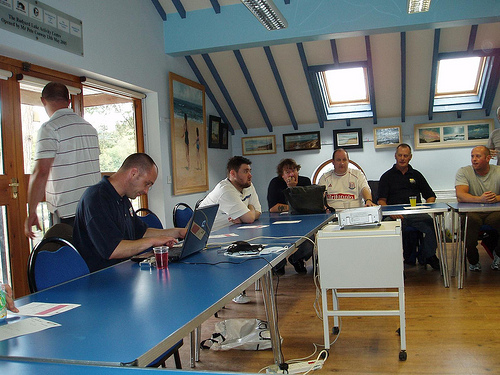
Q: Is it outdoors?
A: Yes, it is outdoors.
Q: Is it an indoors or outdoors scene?
A: It is outdoors.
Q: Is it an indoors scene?
A: No, it is outdoors.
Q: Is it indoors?
A: No, it is outdoors.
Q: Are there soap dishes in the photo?
A: No, there are no soap dishes.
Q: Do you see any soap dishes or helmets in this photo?
A: No, there are no soap dishes or helmets.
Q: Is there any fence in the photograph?
A: No, there are no fences.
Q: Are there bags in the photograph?
A: Yes, there is a bag.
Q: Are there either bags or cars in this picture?
A: Yes, there is a bag.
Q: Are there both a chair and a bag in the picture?
A: Yes, there are both a bag and a chair.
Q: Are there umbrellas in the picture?
A: No, there are no umbrellas.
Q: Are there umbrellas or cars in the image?
A: No, there are no umbrellas or cars.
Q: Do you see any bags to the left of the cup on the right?
A: Yes, there is a bag to the left of the cup.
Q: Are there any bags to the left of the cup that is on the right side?
A: Yes, there is a bag to the left of the cup.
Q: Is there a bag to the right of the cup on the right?
A: No, the bag is to the left of the cup.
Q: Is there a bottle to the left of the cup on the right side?
A: No, there is a bag to the left of the cup.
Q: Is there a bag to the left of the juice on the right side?
A: Yes, there is a bag to the left of the juice.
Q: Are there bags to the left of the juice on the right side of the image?
A: Yes, there is a bag to the left of the juice.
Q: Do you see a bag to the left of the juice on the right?
A: Yes, there is a bag to the left of the juice.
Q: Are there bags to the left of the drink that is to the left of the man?
A: Yes, there is a bag to the left of the juice.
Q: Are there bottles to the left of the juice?
A: No, there is a bag to the left of the juice.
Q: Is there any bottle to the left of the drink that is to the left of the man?
A: No, there is a bag to the left of the juice.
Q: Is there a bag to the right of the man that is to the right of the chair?
A: Yes, there is a bag to the right of the man.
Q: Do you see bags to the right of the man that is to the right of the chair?
A: Yes, there is a bag to the right of the man.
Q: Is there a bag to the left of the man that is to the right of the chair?
A: No, the bag is to the right of the man.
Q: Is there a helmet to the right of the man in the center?
A: No, there is a bag to the right of the man.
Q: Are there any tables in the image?
A: Yes, there is a table.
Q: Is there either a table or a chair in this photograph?
A: Yes, there is a table.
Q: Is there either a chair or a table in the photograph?
A: Yes, there is a table.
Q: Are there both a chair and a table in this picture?
A: Yes, there are both a table and a chair.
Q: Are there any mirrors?
A: No, there are no mirrors.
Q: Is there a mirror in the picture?
A: No, there are no mirrors.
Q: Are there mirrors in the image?
A: No, there are no mirrors.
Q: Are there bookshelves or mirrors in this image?
A: No, there are no mirrors or bookshelves.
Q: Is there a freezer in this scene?
A: No, there are no refrigerators.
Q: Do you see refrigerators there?
A: No, there are no refrigerators.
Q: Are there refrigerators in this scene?
A: No, there are no refrigerators.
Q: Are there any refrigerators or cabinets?
A: No, there are no refrigerators or cabinets.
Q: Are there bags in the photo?
A: Yes, there is a bag.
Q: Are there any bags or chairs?
A: Yes, there is a bag.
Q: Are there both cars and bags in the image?
A: No, there is a bag but no cars.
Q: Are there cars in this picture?
A: No, there are no cars.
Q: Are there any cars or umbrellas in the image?
A: No, there are no cars or umbrellas.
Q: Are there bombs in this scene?
A: No, there are no bombs.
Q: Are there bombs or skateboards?
A: No, there are no bombs or skateboards.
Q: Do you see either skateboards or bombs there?
A: No, there are no bombs or skateboards.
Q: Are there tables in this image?
A: Yes, there is a table.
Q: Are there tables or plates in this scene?
A: Yes, there is a table.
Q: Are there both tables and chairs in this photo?
A: Yes, there are both a table and chairs.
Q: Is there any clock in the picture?
A: No, there are no clocks.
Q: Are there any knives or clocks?
A: No, there are no clocks or knives.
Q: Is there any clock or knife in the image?
A: No, there are no clocks or knives.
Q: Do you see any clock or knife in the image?
A: No, there are no clocks or knives.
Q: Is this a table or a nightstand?
A: This is a table.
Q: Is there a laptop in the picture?
A: Yes, there is a laptop.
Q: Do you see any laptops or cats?
A: Yes, there is a laptop.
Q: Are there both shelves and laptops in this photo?
A: No, there is a laptop but no shelves.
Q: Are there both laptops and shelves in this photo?
A: No, there is a laptop but no shelves.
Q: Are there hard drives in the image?
A: No, there are no hard drives.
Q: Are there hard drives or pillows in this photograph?
A: No, there are no hard drives or pillows.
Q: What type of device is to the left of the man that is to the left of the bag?
A: The device is a laptop.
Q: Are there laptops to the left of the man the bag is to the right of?
A: Yes, there is a laptop to the left of the man.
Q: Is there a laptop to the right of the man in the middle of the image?
A: No, the laptop is to the left of the man.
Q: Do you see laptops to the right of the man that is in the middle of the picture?
A: No, the laptop is to the left of the man.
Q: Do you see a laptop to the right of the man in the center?
A: No, the laptop is to the left of the man.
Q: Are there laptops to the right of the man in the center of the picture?
A: No, the laptop is to the left of the man.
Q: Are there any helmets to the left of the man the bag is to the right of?
A: No, there is a laptop to the left of the man.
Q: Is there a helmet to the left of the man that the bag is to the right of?
A: No, there is a laptop to the left of the man.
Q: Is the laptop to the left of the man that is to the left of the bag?
A: Yes, the laptop is to the left of the man.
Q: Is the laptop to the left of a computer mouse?
A: No, the laptop is to the left of the man.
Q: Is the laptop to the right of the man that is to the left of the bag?
A: No, the laptop is to the left of the man.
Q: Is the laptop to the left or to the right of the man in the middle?
A: The laptop is to the left of the man.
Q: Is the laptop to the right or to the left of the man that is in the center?
A: The laptop is to the left of the man.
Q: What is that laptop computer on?
A: The laptop computer is on the table.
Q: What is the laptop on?
A: The laptop computer is on the table.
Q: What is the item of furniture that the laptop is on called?
A: The piece of furniture is a table.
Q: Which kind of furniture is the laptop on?
A: The laptop is on the table.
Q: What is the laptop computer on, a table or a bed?
A: The laptop computer is on a table.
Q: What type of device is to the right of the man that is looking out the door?
A: The device is a laptop.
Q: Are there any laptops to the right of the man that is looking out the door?
A: Yes, there is a laptop to the right of the man.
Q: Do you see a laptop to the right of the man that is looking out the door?
A: Yes, there is a laptop to the right of the man.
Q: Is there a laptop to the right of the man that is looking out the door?
A: Yes, there is a laptop to the right of the man.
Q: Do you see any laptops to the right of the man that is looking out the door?
A: Yes, there is a laptop to the right of the man.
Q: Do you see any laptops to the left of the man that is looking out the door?
A: No, the laptop is to the right of the man.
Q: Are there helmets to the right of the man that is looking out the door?
A: No, there is a laptop to the right of the man.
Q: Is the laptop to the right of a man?
A: Yes, the laptop is to the right of a man.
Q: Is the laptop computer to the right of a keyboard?
A: No, the laptop computer is to the right of a man.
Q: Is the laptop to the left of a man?
A: No, the laptop is to the right of a man.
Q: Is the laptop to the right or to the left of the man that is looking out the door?
A: The laptop is to the right of the man.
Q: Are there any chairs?
A: Yes, there is a chair.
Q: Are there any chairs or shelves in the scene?
A: Yes, there is a chair.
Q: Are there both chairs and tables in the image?
A: Yes, there are both a chair and a table.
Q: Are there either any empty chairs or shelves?
A: Yes, there is an empty chair.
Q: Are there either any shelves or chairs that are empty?
A: Yes, the chair is empty.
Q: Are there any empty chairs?
A: Yes, there is an empty chair.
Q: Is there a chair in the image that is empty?
A: Yes, there is a chair that is empty.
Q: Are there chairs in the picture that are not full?
A: Yes, there is a empty chair.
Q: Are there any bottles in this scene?
A: No, there are no bottles.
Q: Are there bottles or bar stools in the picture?
A: No, there are no bottles or bar stools.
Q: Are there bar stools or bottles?
A: No, there are no bottles or bar stools.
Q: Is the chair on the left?
A: Yes, the chair is on the left of the image.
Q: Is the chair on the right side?
A: No, the chair is on the left of the image.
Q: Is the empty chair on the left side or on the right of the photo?
A: The chair is on the left of the image.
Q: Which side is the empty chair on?
A: The chair is on the left of the image.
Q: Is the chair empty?
A: Yes, the chair is empty.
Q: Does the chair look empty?
A: Yes, the chair is empty.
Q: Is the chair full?
A: No, the chair is empty.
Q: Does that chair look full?
A: No, the chair is empty.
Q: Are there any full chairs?
A: No, there is a chair but it is empty.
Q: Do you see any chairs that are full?
A: No, there is a chair but it is empty.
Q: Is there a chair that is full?
A: No, there is a chair but it is empty.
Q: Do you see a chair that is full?
A: No, there is a chair but it is empty.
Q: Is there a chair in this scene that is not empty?
A: No, there is a chair but it is empty.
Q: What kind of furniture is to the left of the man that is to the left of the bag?
A: The piece of furniture is a chair.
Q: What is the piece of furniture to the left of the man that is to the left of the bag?
A: The piece of furniture is a chair.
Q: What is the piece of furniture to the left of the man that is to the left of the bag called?
A: The piece of furniture is a chair.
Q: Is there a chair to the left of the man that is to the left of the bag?
A: Yes, there is a chair to the left of the man.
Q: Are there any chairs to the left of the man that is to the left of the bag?
A: Yes, there is a chair to the left of the man.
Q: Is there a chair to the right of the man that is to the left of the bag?
A: No, the chair is to the left of the man.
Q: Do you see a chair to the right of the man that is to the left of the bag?
A: No, the chair is to the left of the man.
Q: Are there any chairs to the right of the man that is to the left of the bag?
A: No, the chair is to the left of the man.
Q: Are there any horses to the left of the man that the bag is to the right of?
A: No, there is a chair to the left of the man.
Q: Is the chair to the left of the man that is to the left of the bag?
A: Yes, the chair is to the left of the man.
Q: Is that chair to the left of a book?
A: No, the chair is to the left of the man.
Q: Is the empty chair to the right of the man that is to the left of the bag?
A: No, the chair is to the left of the man.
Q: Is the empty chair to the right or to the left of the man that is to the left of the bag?
A: The chair is to the left of the man.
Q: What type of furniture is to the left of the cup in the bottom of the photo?
A: The piece of furniture is a chair.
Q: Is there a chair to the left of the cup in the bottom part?
A: Yes, there is a chair to the left of the cup.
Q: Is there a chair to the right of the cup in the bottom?
A: No, the chair is to the left of the cup.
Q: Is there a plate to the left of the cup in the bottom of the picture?
A: No, there is a chair to the left of the cup.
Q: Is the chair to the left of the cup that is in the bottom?
A: Yes, the chair is to the left of the cup.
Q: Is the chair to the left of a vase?
A: No, the chair is to the left of the cup.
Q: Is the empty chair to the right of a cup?
A: No, the chair is to the left of a cup.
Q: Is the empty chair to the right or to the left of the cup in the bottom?
A: The chair is to the left of the cup.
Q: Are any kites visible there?
A: No, there are no kites.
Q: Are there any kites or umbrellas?
A: No, there are no kites or umbrellas.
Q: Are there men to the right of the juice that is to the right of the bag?
A: Yes, there is a man to the right of the juice.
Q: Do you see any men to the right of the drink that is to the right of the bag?
A: Yes, there is a man to the right of the juice.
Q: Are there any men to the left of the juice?
A: No, the man is to the right of the juice.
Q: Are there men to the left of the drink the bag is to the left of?
A: No, the man is to the right of the juice.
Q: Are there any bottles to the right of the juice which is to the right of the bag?
A: No, there is a man to the right of the juice.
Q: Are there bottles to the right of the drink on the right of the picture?
A: No, there is a man to the right of the juice.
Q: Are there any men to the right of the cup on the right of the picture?
A: Yes, there is a man to the right of the cup.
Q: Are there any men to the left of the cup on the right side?
A: No, the man is to the right of the cup.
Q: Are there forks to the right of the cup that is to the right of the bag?
A: No, there is a man to the right of the cup.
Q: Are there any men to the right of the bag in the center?
A: Yes, there is a man to the right of the bag.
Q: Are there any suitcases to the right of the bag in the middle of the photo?
A: No, there is a man to the right of the bag.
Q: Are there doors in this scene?
A: Yes, there is a door.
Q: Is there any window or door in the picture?
A: Yes, there is a door.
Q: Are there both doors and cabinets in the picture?
A: No, there is a door but no cabinets.